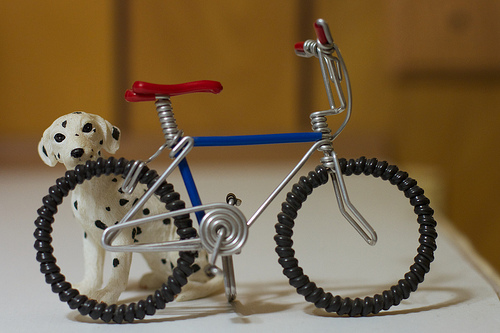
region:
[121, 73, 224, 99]
The bicycle seat is red.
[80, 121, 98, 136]
The dog's eye is black.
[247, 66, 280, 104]
The wall in the background is yellow.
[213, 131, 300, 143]
The bike frame is blue.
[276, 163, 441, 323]
The front bike wheel is black.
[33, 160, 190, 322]
The back bike wheel is black.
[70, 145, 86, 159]
The dogs nose is black.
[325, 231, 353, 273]
The table is white.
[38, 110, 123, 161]
The dogs face is black and white.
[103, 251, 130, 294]
The dogs leg has one black spot.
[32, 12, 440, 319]
Miniature bike make with paper clips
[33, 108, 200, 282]
Dog has black and white spots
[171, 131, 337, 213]
Bike has blue body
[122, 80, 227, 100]
Bike has red seat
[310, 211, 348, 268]
Bike is sitting on white shelf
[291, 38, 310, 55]
Bike has red hand grips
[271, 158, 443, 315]
Tires on the bike is made with phone cord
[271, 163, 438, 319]
The phone cord on the tires is black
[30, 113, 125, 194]
The dog is getting ready to chew on tire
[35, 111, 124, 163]
Dog has black nose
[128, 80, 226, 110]
bicycle has red seat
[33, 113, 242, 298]
dog stands behind bicycle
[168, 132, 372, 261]
bike has blue frame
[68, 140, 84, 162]
dog has black nose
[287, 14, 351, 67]
handle bars are red in color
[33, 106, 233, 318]
dog is black and white in color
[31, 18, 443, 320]
items are on a table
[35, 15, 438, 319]
bicycle is a little replica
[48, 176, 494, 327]
table is white in color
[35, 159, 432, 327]
tires on bicycle are black in color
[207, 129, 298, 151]
The bicycle frame is blue.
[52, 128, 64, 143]
The dogs eye is black.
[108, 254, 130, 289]
The dogs leg has one spot.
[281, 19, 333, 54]
The handle bars are red and silver.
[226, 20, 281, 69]
The wall in the background is orange.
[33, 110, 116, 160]
The dogs face is spotted.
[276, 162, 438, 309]
The front bicycle wheel is black.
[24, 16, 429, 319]
Miniature bicycle replica.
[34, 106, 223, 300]
Plastic dalmatian dog on table.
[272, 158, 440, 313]
Black wheel of the bike.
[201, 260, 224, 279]
Silver pedal on the bike.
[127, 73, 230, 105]
Red seat on the bike.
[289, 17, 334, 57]
Red handle grips on the bike.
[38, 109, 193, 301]
Back spots on the dog.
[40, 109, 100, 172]
Black eyes on the dog.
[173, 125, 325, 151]
Blue bar on the bike.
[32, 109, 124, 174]
Black nose on the dog.